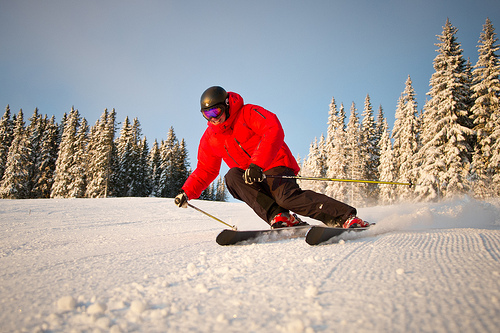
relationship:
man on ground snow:
[174, 85, 374, 229] [2, 24, 499, 195]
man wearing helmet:
[174, 85, 374, 229] [198, 85, 229, 110]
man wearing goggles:
[174, 85, 374, 229] [199, 94, 231, 121]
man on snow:
[174, 85, 374, 229] [2, 198, 497, 333]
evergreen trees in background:
[315, 28, 499, 199] [0, 105, 226, 204]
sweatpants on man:
[222, 164, 357, 223] [174, 85, 374, 229]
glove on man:
[241, 162, 267, 187] [174, 85, 374, 229]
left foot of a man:
[263, 203, 305, 234] [174, 85, 374, 229]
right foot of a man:
[333, 210, 375, 234] [174, 85, 374, 229]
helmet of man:
[197, 81, 236, 103] [174, 85, 374, 229]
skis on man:
[210, 219, 384, 243] [174, 85, 374, 229]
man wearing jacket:
[174, 85, 374, 229] [181, 91, 301, 198]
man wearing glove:
[174, 85, 374, 229] [241, 162, 267, 187]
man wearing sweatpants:
[182, 92, 299, 172] [222, 164, 358, 226]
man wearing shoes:
[174, 85, 374, 229] [255, 206, 367, 228]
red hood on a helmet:
[226, 90, 246, 124] [199, 86, 229, 128]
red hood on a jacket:
[228, 87, 245, 124] [182, 95, 299, 176]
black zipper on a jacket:
[231, 136, 256, 161] [181, 91, 301, 198]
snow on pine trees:
[2, 54, 499, 195] [3, 101, 188, 199]